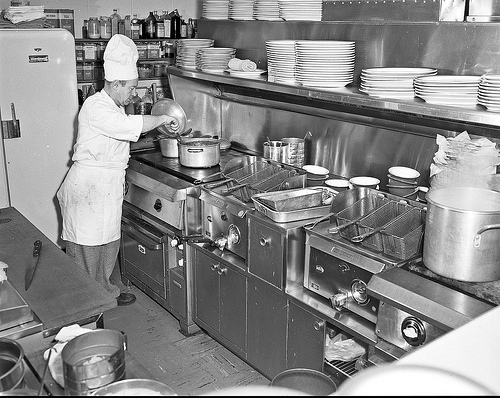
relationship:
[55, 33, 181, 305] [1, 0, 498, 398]
chef inside kitchen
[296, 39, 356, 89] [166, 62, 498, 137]
dishes on top of shelf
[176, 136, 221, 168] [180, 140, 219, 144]
pot contains soup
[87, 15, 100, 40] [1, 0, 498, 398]
spice inside of kitchen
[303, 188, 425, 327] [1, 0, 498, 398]
fryer inside of kitchen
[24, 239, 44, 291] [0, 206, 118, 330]
knife on top of cutting board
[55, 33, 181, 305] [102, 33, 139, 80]
chef wearing hat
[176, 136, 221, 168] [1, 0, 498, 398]
pot inside kitchen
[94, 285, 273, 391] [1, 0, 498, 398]
floor on bottom of kitchen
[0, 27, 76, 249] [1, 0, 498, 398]
fridge inside of kitchen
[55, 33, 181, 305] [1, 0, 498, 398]
chef cooking inside kitchen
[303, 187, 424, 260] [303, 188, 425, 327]
basket on top of fryer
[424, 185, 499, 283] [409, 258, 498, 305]
pot on top of counter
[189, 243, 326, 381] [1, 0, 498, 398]
cabinets inside of kitchen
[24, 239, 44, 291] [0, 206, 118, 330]
knife on top of table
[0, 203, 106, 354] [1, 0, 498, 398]
table inside of kitchen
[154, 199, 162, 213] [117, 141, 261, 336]
dial on front of stove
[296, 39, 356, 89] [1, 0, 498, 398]
plates inside of kitchen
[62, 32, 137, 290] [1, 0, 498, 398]
man inside of kitchen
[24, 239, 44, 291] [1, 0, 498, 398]
knife inside of kitchen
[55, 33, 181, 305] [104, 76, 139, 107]
man with light skin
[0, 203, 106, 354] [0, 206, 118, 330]
table made of wood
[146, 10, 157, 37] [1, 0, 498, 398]
bottle inside of kitchen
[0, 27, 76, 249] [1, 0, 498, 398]
refrigerator inside of kitchen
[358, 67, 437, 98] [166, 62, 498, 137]
plates on top of shelf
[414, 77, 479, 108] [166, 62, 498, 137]
plates on top of shelf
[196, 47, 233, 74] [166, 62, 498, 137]
plates on top of shelf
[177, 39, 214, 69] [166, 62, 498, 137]
plates on top of shelf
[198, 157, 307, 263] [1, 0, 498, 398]
fryer inside of kitchen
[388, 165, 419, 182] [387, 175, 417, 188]
soup bowl on top of soup bowl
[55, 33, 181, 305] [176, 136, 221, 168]
chef making food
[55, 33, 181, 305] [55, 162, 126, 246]
man wearing apron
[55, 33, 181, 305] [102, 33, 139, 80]
man wearing hat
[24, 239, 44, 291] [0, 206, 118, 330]
chef knife on top of butcherblock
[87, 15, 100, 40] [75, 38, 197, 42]
spice on top of shelf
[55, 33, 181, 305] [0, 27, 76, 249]
chef next to refrigirator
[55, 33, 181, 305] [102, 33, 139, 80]
man wearing chef hat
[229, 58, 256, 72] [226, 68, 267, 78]
towl on top of plate